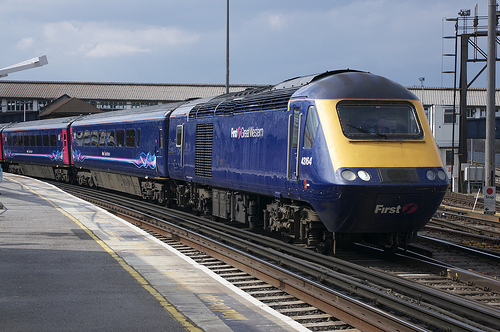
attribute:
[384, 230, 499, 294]
track — rusty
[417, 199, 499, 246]
track — rusty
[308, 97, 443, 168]
train part — yellow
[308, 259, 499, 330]
railroad track — steel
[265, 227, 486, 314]
track — steel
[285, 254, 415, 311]
tracks — rusty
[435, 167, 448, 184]
light — white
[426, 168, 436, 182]
light — white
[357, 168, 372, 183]
light — white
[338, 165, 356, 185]
light — white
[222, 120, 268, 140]
lettering — white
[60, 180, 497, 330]
track — rusty